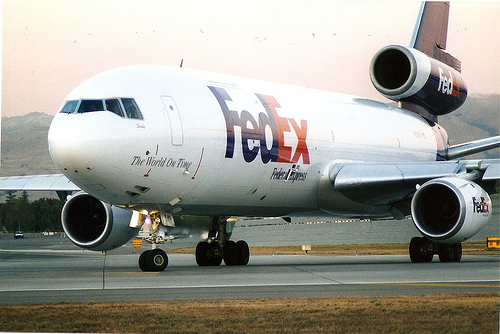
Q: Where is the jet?
A: On the runway.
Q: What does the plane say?
A: Fedex.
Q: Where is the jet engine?
A: On the wings.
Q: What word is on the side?
A: FedEx.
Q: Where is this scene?
A: Airport.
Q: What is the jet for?
A: Delivery.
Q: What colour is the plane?
A: White.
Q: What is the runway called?
A: Taxiway.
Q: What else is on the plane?
A: Other words.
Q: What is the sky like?
A: Overcast.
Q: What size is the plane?
A: Large.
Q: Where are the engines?
A: Sides.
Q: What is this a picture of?
A: A large plane on a runway, outside.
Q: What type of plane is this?
A: A FedEx plane.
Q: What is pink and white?
A: The sky.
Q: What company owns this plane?
A: Fedex.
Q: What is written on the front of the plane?
A: The World On Time.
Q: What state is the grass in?
A: It is dead.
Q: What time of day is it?
A: Sunset.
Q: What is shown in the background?
A: Mountains.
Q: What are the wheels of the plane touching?
A: The tarmac.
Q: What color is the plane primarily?
A: White.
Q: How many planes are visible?
A: One.